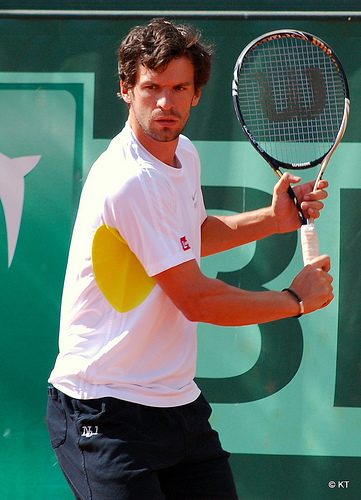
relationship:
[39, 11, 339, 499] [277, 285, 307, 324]
man has bracelet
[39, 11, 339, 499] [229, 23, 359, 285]
man holding racket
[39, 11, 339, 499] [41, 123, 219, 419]
man wearing shirt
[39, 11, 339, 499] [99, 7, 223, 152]
man has brown hair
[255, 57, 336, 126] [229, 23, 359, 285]
w on racket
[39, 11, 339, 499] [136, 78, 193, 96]
man has eyes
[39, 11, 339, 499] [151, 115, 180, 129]
man has mouth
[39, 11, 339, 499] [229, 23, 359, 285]
man holding racquet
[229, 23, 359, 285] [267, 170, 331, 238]
racket on hand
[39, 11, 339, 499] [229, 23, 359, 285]
man with a racquet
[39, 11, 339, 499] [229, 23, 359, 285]
man has racquet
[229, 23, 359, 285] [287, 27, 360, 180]
racket black orange and white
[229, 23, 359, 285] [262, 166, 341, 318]
racket in player's hands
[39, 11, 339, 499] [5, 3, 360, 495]
player on court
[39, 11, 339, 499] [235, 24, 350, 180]
player preparing to hit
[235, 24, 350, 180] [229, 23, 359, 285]
net on raquet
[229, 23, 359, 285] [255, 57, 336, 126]
racket has w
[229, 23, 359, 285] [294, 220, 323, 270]
raquet has handle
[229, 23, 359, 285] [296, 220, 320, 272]
racquet has handle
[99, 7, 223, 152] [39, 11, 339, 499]
head of man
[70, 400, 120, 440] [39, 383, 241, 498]
pocket on pants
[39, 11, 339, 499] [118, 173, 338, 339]
man has arm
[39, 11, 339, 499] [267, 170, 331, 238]
man has hand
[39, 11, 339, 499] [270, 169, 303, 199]
man has thumb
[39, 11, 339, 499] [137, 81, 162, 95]
man has eye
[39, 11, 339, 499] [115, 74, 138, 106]
man has ear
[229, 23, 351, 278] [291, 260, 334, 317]
racket in player's hands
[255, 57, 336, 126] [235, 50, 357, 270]
logo on racket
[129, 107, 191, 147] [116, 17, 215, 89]
chin has brown hair